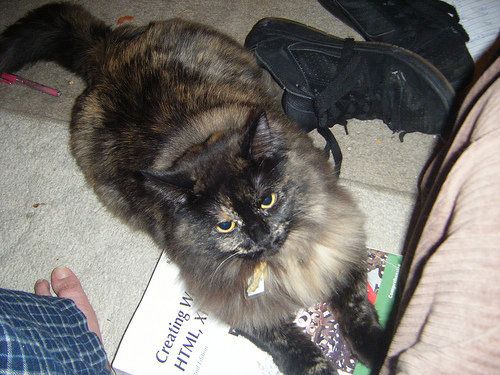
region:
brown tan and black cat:
[5, 5, 390, 374]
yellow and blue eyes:
[215, 185, 290, 235]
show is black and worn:
[243, 10, 459, 176]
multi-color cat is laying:
[0, 3, 472, 373]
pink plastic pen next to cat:
[0, 62, 68, 93]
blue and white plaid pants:
[0, 286, 110, 371]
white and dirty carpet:
[0, 0, 436, 372]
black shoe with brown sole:
[247, 11, 469, 147]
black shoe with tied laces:
[242, 12, 462, 165]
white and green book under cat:
[112, 200, 441, 372]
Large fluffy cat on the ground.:
[1, 3, 388, 370]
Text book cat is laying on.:
[110, 218, 410, 373]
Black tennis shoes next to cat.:
[240, 1, 483, 172]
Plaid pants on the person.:
[1, 285, 119, 372]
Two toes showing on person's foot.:
[31, 269, 103, 349]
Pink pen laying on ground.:
[2, 66, 64, 101]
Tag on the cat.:
[237, 260, 273, 298]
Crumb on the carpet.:
[65, 73, 80, 90]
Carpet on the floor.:
[1, 0, 444, 374]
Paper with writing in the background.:
[443, 3, 499, 64]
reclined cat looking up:
[64, 25, 376, 345]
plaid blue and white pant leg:
[3, 292, 92, 367]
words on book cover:
[153, 296, 203, 372]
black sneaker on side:
[248, 16, 453, 134]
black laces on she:
[313, 54, 368, 173]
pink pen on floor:
[3, 68, 66, 104]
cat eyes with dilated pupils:
[204, 190, 289, 239]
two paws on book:
[251, 291, 384, 373]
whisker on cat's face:
[200, 239, 252, 288]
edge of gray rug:
[355, 172, 405, 207]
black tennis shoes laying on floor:
[256, 0, 470, 153]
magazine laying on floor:
[97, 245, 193, 372]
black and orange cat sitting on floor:
[62, 25, 399, 367]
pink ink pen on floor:
[2, 67, 70, 97]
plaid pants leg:
[0, 303, 100, 373]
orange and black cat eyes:
[203, 168, 292, 255]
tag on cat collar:
[233, 264, 271, 308]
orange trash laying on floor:
[111, 6, 143, 25]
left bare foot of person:
[25, 255, 125, 373]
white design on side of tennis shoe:
[382, 61, 410, 89]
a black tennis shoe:
[226, 5, 443, 125]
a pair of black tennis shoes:
[247, 7, 478, 124]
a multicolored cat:
[128, 74, 348, 339]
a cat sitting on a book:
[127, 121, 374, 373]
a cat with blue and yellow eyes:
[156, 169, 283, 269]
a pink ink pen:
[0, 55, 67, 113]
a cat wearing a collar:
[163, 135, 314, 347]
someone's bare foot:
[18, 252, 93, 359]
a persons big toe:
[52, 246, 76, 321]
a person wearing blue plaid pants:
[4, 280, 90, 371]